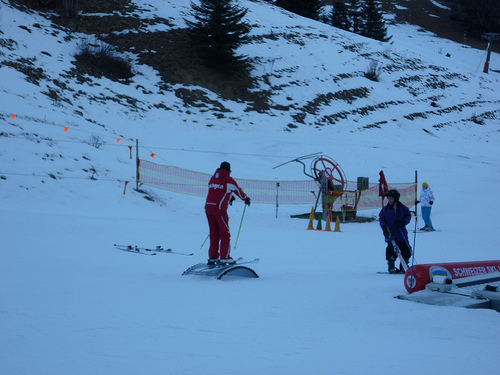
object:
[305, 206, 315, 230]
cone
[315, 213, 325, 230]
cone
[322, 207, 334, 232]
cone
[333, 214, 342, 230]
cone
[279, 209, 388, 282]
snow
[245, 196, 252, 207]
glove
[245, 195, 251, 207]
hand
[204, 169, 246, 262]
snowsuit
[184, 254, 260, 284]
surface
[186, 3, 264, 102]
tree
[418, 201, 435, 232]
pants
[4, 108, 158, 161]
flag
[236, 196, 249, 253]
pole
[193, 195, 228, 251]
pole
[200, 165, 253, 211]
jacket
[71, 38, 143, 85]
patches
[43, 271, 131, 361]
snow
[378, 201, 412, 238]
coat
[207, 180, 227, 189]
lettering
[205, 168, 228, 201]
background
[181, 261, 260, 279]
skis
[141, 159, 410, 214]
barrier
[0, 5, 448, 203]
hillside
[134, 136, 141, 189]
pole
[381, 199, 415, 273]
suit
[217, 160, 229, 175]
helmet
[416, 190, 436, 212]
coat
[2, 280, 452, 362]
ground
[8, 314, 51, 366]
snow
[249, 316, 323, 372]
snow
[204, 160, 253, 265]
man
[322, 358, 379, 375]
snow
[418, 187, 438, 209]
jacket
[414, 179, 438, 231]
person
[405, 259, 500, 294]
object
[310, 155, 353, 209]
fan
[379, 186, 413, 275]
person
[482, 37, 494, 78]
post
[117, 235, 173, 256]
skis